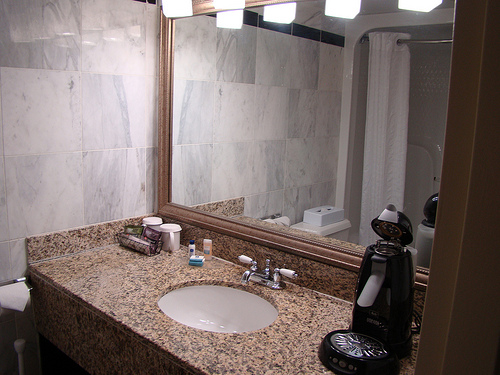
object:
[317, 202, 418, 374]
coffee maker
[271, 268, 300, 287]
handle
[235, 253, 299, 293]
faucet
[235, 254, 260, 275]
handle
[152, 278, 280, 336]
sink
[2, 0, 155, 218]
wall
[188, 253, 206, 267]
soap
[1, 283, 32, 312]
toilet paper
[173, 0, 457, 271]
mirror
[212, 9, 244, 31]
light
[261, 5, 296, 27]
light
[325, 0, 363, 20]
light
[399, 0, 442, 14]
light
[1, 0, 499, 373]
bathroom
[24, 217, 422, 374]
counter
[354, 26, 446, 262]
shower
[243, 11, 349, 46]
strip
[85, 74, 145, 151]
tile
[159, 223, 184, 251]
cup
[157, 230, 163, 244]
corner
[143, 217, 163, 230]
cup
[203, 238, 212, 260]
toiletries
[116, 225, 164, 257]
basket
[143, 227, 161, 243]
soaps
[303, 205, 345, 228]
box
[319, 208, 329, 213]
kleenex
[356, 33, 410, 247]
curtains